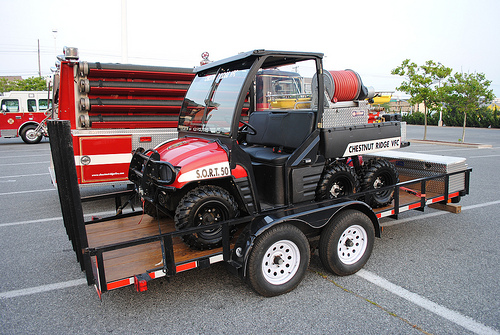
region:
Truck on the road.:
[46, 46, 470, 328]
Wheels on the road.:
[198, 201, 383, 333]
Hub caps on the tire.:
[245, 204, 311, 312]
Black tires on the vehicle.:
[219, 205, 494, 316]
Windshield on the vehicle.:
[153, 49, 290, 150]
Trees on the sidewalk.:
[339, 50, 489, 220]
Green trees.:
[393, 44, 495, 152]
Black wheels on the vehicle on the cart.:
[133, 115, 271, 257]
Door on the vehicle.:
[176, 44, 379, 210]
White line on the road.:
[383, 227, 410, 317]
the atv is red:
[173, 145, 201, 159]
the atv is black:
[263, 175, 283, 195]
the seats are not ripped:
[259, 122, 292, 134]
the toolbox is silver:
[331, 113, 351, 123]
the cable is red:
[332, 72, 352, 88]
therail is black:
[131, 231, 186, 261]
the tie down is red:
[402, 181, 419, 199]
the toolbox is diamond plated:
[401, 156, 420, 181]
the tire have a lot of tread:
[361, 159, 381, 176]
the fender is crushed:
[240, 231, 260, 271]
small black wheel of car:
[159, 187, 245, 246]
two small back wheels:
[294, 155, 403, 207]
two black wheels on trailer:
[228, 206, 384, 286]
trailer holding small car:
[33, 35, 475, 290]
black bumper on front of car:
[123, 148, 172, 184]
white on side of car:
[181, 156, 231, 190]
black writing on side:
[196, 159, 236, 180]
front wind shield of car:
[176, 62, 248, 126]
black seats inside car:
[249, 109, 297, 173]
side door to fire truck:
[0, 94, 23, 139]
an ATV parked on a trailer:
[43, 61, 480, 303]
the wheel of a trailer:
[248, 223, 313, 294]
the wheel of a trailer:
[324, 208, 374, 280]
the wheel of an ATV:
[176, 190, 239, 247]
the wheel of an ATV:
[320, 167, 359, 204]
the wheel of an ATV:
[358, 162, 398, 205]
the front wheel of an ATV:
[167, 187, 238, 248]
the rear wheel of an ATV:
[321, 155, 358, 202]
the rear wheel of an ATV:
[364, 157, 403, 204]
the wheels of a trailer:
[244, 201, 381, 298]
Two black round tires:
[243, 207, 376, 300]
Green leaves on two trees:
[390, 56, 496, 143]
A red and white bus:
[1, 89, 58, 147]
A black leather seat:
[240, 109, 317, 168]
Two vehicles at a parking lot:
[1, 40, 498, 332]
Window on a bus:
[0, 95, 22, 115]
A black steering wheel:
[235, 112, 260, 142]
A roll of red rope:
[310, 67, 365, 105]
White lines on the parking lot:
[1, 145, 497, 333]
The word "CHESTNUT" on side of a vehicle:
[346, 139, 376, 155]